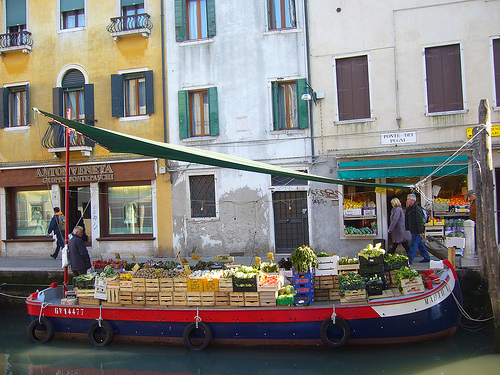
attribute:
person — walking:
[385, 190, 409, 260]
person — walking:
[401, 187, 431, 254]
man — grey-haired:
[405, 194, 432, 266]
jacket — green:
[405, 202, 425, 232]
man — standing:
[59, 222, 99, 280]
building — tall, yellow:
[1, 2, 173, 271]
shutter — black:
[111, 71, 126, 118]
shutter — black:
[145, 70, 153, 113]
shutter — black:
[20, 82, 28, 123]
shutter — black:
[1, 84, 9, 125]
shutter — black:
[85, 82, 92, 126]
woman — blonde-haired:
[384, 195, 411, 265]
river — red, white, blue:
[3, 305, 498, 372]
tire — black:
[320, 315, 350, 347]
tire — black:
[183, 317, 210, 349]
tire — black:
[88, 317, 115, 345]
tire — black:
[27, 319, 56, 339]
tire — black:
[174, 314, 217, 351]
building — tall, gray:
[158, 4, 325, 274]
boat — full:
[55, 199, 454, 354]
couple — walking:
[386, 194, 431, 264]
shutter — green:
[270, 78, 309, 131]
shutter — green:
[180, 84, 220, 138]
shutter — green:
[264, 0, 295, 30]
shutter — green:
[175, 0, 217, 44]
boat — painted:
[36, 239, 463, 350]